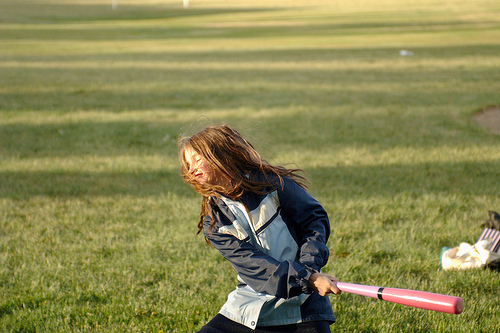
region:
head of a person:
[168, 123, 250, 188]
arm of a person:
[208, 219, 288, 311]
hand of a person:
[310, 262, 341, 309]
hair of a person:
[203, 125, 263, 177]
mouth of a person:
[186, 170, 205, 187]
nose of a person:
[186, 159, 198, 182]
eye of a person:
[189, 152, 214, 173]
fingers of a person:
[319, 268, 341, 318]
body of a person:
[180, 185, 373, 292]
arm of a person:
[285, 180, 349, 255]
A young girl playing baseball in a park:
[172, 115, 467, 331]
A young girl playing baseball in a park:
[163, 115, 469, 331]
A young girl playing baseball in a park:
[165, 117, 470, 325]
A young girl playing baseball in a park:
[165, 120, 466, 328]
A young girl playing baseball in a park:
[160, 115, 490, 325]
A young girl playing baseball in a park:
[165, 112, 463, 329]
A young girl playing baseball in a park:
[167, 115, 475, 326]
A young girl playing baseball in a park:
[173, 112, 471, 327]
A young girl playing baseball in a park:
[176, 120, 471, 330]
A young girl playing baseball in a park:
[167, 116, 470, 331]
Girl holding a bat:
[303, 263, 457, 322]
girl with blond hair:
[158, 101, 263, 214]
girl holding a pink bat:
[283, 241, 485, 331]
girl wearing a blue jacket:
[194, 175, 337, 307]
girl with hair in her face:
[171, 131, 235, 201]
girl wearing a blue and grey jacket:
[205, 211, 319, 306]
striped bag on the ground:
[471, 223, 497, 248]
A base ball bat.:
[333, 279, 464, 316]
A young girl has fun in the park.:
[176, 125, 351, 328]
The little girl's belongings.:
[439, 210, 497, 270]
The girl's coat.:
[220, 210, 319, 312]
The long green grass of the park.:
[18, 199, 188, 309]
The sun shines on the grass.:
[25, 204, 182, 278]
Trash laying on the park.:
[400, 39, 417, 61]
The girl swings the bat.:
[258, 240, 471, 320]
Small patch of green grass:
[10, 281, 75, 331]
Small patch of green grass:
[72, 280, 122, 323]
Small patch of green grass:
[119, 275, 164, 316]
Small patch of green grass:
[65, 166, 116, 211]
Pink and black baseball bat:
[321, 280, 471, 330]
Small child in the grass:
[170, 108, 291, 330]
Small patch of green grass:
[21, 27, 76, 65]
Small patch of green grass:
[89, 30, 146, 65]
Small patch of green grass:
[147, 27, 243, 73]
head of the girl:
[146, 93, 292, 198]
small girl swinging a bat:
[179, 124, 337, 332]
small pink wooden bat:
[331, 281, 461, 313]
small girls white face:
[185, 142, 217, 184]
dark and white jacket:
[202, 177, 339, 326]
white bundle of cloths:
[434, 240, 499, 270]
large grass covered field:
[0, 3, 497, 332]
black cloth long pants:
[192, 313, 331, 332]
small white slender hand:
[316, 269, 339, 300]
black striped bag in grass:
[476, 221, 498, 268]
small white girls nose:
[188, 162, 196, 172]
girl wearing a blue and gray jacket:
[171, 140, 330, 321]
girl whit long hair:
[171, 140, 308, 325]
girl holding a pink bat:
[181, 128, 375, 330]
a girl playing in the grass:
[173, 140, 418, 317]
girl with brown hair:
[168, 128, 270, 207]